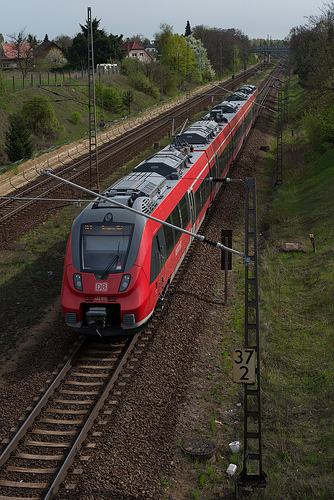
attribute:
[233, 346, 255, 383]
numbers — Black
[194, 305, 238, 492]
grass — green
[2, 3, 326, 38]
skies — Grayish,  overhead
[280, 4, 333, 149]
trees —  Group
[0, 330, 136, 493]
tracks —  railroad's 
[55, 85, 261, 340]
cars —  five ,  train's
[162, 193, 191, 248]
windows —   dark,  in row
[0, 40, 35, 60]
roof —  house's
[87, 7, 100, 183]
structure —  metal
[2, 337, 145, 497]
tracks —  two,   train's ,  train's 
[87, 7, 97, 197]
structure —  metal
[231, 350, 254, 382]
372 — of  sign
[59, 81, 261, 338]
train —  passenger's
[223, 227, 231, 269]
sign —  road's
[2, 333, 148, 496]
track —  train's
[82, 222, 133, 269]
windshield —  train's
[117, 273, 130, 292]
headlight —  train's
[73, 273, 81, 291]
headlight —  train's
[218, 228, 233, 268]
back — of a train signal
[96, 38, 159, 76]
houses — in the background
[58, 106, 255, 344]
train — red and grey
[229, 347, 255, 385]
sign — with number on it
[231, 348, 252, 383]
numbers — 37 and 2